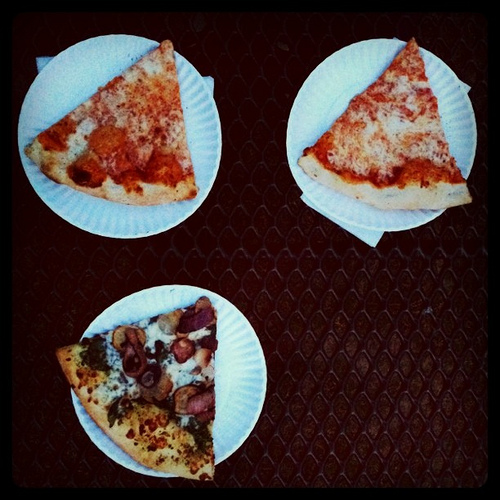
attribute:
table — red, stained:
[17, 12, 479, 494]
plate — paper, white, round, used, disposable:
[15, 43, 233, 244]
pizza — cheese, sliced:
[38, 60, 199, 213]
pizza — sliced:
[64, 296, 231, 480]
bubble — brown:
[65, 162, 98, 186]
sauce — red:
[144, 149, 182, 169]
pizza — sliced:
[294, 41, 480, 209]